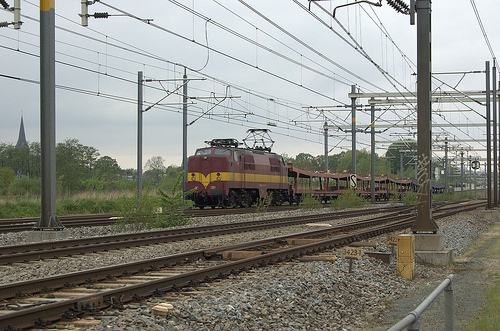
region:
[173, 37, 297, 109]
wires above the train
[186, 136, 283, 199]
red and white train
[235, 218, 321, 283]
track next to the rocks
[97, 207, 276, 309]
tracks on the ground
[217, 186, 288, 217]
bottom part of the train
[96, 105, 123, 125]
sky in the background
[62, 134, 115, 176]
trees in the distance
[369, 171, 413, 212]
back part of the train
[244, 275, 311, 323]
rocks next to the train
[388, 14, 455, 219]
pole next to the track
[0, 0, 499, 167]
cloud cover in sky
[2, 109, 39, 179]
gray steeple behind trees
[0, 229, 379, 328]
metal rails in gravel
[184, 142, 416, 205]
engine of freight train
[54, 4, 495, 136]
wires and metal frames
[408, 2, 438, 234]
pole with graffiti at bottom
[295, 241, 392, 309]
sign in gravel hill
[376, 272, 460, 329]
top of metal rail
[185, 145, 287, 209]
red and yellow train engine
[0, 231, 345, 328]
two sets of train tracks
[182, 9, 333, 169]
wires above the train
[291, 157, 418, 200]
the train cars are empty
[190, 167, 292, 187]
stripe on the train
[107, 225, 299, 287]
the tracks are iron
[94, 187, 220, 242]
bushes in the gravel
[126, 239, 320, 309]
tracks in the gravel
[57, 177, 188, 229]
grass beside the tracks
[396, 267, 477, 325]
the rail is silver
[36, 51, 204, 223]
poles beside the tracks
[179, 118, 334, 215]
train is on the tracks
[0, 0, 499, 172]
A grey cloudy sky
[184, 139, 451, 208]
A red and yellow train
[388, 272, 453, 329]
some metal railing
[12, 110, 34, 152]
A spire in the distance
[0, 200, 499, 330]
Some gravel on the train tracks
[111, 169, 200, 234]
some small bushes on the tracks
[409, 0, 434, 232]
A large metal pole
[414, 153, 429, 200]
some graffiti on a metal pole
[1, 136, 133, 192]
Some trees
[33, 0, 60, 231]
A large metal pole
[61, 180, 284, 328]
These are train tracks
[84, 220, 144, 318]
The tracks are steel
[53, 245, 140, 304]
The tracks are rusty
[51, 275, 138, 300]
These are pieces of wood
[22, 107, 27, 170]
This is a building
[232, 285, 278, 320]
These are pieces of rocks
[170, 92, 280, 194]
This is a train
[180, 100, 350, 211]
This is the first car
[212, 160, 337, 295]
The car is maroon and yellow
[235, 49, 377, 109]
These are cables